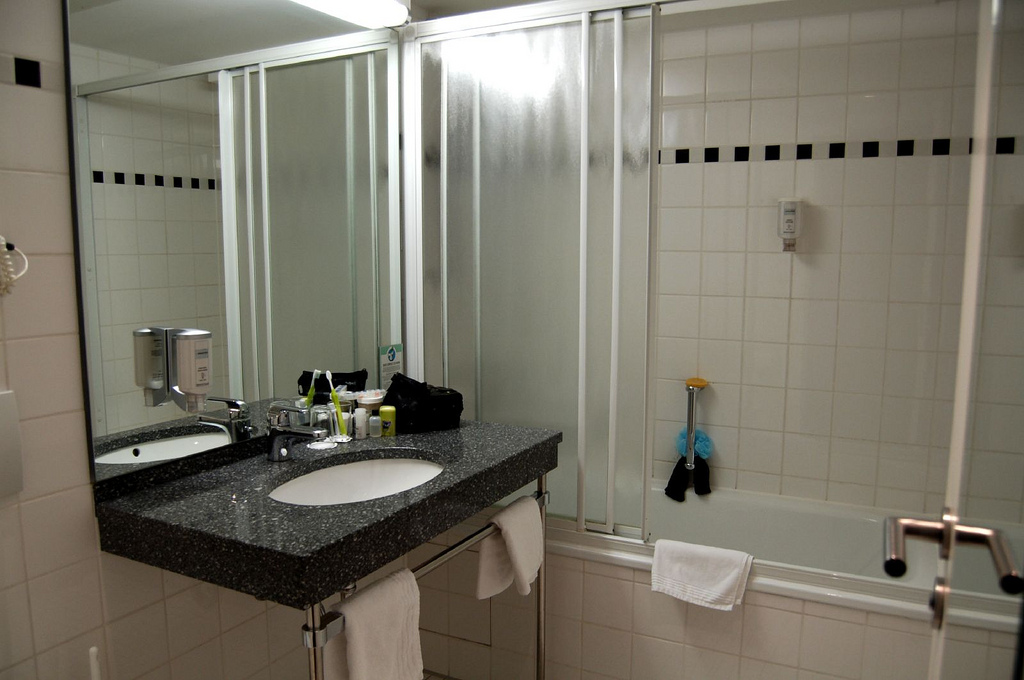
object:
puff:
[676, 426, 713, 460]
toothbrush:
[323, 370, 357, 443]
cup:
[326, 400, 352, 439]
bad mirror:
[50, 1, 423, 492]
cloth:
[475, 495, 545, 600]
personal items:
[380, 405, 396, 438]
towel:
[651, 539, 752, 614]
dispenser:
[164, 326, 214, 413]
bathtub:
[538, 457, 1023, 607]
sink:
[264, 446, 447, 507]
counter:
[96, 416, 573, 611]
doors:
[417, 0, 649, 540]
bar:
[414, 543, 483, 585]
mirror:
[65, 0, 428, 488]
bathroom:
[0, 0, 1024, 680]